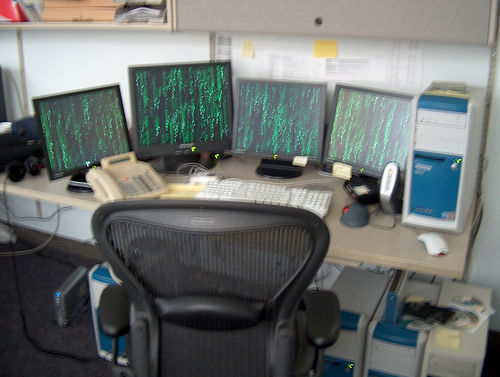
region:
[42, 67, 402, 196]
monitors on the desk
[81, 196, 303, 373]
the chair is black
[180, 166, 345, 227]
keyboard on the desk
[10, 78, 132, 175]
Small black computer monitor on white desk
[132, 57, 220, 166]
Small black computer monitor on white desk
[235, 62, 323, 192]
Small black computer monitor on white desk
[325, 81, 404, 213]
Small black computer monitor on white desk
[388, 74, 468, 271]
White and blue computer tower on desk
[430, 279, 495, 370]
White and blue computer tower on floor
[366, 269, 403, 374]
White and blue computer tower on floor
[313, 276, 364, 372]
White and blue computer tower on floor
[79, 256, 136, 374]
White and blue computer tower on floor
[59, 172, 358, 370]
Small black desk chair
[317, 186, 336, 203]
key on a keyboard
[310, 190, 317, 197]
key on a keyboard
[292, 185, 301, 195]
key on a keyboard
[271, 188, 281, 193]
key on a keyboard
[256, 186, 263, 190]
key on a keyboard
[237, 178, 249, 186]
key on a keyboard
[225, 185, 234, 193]
key on a keyboard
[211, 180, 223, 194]
key on a keyboard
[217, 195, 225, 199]
key on a keyboard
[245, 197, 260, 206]
key on a keyboard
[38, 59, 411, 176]
four computer monitors in a row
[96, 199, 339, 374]
back of office chair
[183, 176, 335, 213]
white keyboard on desk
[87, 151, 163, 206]
office phone on desk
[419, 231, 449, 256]
top of computer mouse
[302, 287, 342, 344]
black armrest on chair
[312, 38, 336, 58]
yellow note paper on wall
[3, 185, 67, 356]
hanging wires of electronics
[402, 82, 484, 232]
blue and white computer tower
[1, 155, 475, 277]
flat surface of desk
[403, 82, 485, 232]
a blue and white CPU on the desk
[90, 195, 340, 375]
a black executive desk chair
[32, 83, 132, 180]
a black flat screen computer monitor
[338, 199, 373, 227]
a computer scrolling mouse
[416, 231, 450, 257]
a white wireless mouse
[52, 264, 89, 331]
a grey computer router modem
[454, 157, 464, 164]
the green power light on the CPU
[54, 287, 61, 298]
the modem's blue power light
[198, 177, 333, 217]
the beige computer keyboard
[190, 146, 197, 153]
the green power light of the computer monitor